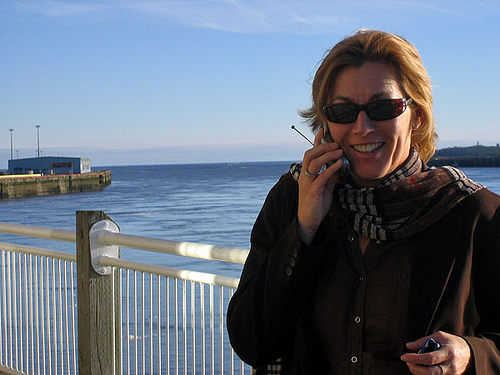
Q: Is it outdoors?
A: Yes, it is outdoors.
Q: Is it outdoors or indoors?
A: It is outdoors.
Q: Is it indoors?
A: No, it is outdoors.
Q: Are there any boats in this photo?
A: No, there are no boats.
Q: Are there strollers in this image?
A: No, there are no strollers.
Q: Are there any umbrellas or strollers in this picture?
A: No, there are no strollers or umbrellas.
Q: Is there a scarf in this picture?
A: Yes, there is a scarf.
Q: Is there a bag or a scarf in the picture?
A: Yes, there is a scarf.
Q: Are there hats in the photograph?
A: No, there are no hats.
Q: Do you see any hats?
A: No, there are no hats.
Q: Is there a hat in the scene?
A: No, there are no hats.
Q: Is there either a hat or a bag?
A: No, there are no hats or bags.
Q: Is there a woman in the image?
A: Yes, there is a woman.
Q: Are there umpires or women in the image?
A: Yes, there is a woman.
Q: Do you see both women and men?
A: No, there is a woman but no men.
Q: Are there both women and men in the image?
A: No, there is a woman but no men.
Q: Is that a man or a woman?
A: That is a woman.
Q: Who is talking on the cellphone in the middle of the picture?
A: The woman is talking on the cellphone.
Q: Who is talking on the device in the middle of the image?
A: The woman is talking on the cellphone.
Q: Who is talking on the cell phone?
A: The woman is talking on the cellphone.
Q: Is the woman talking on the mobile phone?
A: Yes, the woman is talking on the mobile phone.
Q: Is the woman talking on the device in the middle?
A: Yes, the woman is talking on the mobile phone.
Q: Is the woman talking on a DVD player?
A: No, the woman is talking on the mobile phone.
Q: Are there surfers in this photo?
A: No, there are no surfers.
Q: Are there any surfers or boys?
A: No, there are no surfers or boys.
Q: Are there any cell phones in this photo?
A: Yes, there is a cell phone.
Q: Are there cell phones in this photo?
A: Yes, there is a cell phone.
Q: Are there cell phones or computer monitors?
A: Yes, there is a cell phone.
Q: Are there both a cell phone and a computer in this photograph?
A: No, there is a cell phone but no computers.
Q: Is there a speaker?
A: No, there are no speakers.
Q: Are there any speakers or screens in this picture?
A: No, there are no speakers or screens.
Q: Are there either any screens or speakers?
A: No, there are no speakers or screens.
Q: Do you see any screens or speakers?
A: No, there are no speakers or screens.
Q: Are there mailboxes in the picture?
A: No, there are no mailboxes.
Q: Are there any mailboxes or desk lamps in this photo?
A: No, there are no mailboxes or desk lamps.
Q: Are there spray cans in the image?
A: No, there are no spray cans.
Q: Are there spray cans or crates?
A: No, there are no spray cans or crates.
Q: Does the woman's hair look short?
A: Yes, the hair is short.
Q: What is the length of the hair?
A: The hair is short.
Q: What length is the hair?
A: The hair is short.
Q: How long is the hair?
A: The hair is short.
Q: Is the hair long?
A: No, the hair is short.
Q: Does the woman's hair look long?
A: No, the hair is short.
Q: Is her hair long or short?
A: The hair is short.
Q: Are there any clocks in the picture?
A: No, there are no clocks.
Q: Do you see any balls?
A: No, there are no balls.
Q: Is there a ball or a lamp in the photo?
A: No, there are no balls or lamps.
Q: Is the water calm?
A: Yes, the water is calm.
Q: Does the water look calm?
A: Yes, the water is calm.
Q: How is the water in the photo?
A: The water is calm.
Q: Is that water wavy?
A: No, the water is calm.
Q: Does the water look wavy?
A: No, the water is calm.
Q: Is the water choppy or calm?
A: The water is calm.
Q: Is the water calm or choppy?
A: The water is calm.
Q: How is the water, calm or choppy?
A: The water is calm.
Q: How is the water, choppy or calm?
A: The water is calm.